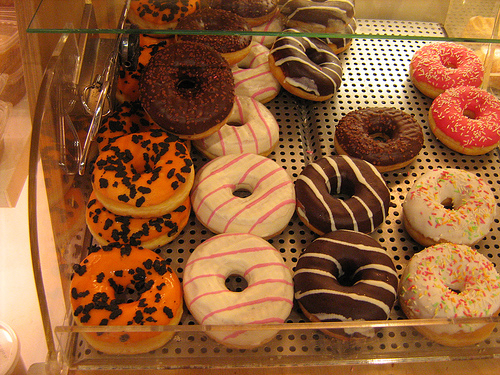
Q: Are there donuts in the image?
A: Yes, there are donuts.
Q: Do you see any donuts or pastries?
A: Yes, there are donuts.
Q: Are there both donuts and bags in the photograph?
A: No, there are donuts but no bags.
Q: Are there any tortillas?
A: No, there are no tortillas.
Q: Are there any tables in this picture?
A: Yes, there is a table.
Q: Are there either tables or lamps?
A: Yes, there is a table.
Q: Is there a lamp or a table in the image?
A: Yes, there is a table.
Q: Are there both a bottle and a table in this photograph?
A: No, there is a table but no bottles.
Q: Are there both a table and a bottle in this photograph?
A: No, there is a table but no bottles.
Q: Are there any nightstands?
A: No, there are no nightstands.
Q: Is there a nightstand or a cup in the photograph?
A: No, there are no nightstands or cups.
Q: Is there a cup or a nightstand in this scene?
A: No, there are no nightstands or cups.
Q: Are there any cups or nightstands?
A: No, there are no nightstands or cups.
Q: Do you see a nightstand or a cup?
A: No, there are no nightstands or cups.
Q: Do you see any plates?
A: Yes, there is a plate.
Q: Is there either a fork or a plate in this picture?
A: Yes, there is a plate.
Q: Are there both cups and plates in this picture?
A: No, there is a plate but no cups.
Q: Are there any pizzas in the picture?
A: No, there are no pizzas.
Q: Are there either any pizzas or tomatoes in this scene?
A: No, there are no pizzas or tomatoes.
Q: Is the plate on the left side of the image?
A: Yes, the plate is on the left of the image.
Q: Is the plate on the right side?
A: No, the plate is on the left of the image.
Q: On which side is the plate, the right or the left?
A: The plate is on the left of the image.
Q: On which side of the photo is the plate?
A: The plate is on the left of the image.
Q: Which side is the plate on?
A: The plate is on the left of the image.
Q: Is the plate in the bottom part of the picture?
A: Yes, the plate is in the bottom of the image.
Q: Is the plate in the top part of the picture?
A: No, the plate is in the bottom of the image.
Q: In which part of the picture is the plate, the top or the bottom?
A: The plate is in the bottom of the image.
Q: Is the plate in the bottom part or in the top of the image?
A: The plate is in the bottom of the image.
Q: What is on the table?
A: The plate is on the table.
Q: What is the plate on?
A: The plate is on the table.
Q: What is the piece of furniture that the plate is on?
A: The piece of furniture is a table.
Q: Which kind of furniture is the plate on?
A: The plate is on the table.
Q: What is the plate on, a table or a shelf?
A: The plate is on a table.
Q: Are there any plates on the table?
A: Yes, there is a plate on the table.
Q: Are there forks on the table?
A: No, there is a plate on the table.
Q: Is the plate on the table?
A: Yes, the plate is on the table.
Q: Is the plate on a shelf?
A: No, the plate is on the table.